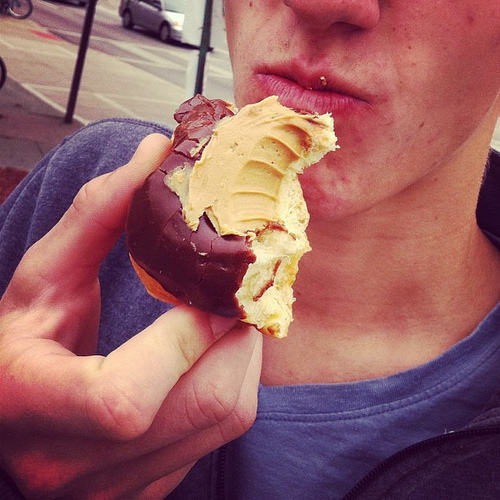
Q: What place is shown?
A: It is a city.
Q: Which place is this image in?
A: It is at the city.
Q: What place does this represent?
A: It represents the city.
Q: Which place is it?
A: It is a city.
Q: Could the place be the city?
A: Yes, it is the city.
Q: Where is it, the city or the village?
A: It is the city.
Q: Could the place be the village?
A: No, it is the city.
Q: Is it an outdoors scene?
A: Yes, it is outdoors.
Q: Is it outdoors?
A: Yes, it is outdoors.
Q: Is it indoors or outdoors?
A: It is outdoors.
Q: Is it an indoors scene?
A: No, it is outdoors.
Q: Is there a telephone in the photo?
A: No, there are no phones.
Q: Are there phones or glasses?
A: No, there are no phones or glasses.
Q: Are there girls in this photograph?
A: No, there are no girls.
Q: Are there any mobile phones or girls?
A: No, there are no girls or mobile phones.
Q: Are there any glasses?
A: No, there are no glasses.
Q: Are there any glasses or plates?
A: No, there are no glasses or plates.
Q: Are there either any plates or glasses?
A: No, there are no glasses or plates.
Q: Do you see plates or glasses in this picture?
A: No, there are no glasses or plates.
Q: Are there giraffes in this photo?
A: No, there are no giraffes.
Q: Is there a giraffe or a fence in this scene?
A: No, there are no giraffes or fences.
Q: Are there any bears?
A: No, there are no bears.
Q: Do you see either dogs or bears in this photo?
A: No, there are no bears or dogs.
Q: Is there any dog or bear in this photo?
A: No, there are no bears or dogs.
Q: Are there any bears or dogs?
A: No, there are no bears or dogs.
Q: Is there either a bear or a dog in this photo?
A: No, there are no bears or dogs.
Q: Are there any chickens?
A: No, there are no chickens.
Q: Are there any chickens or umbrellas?
A: No, there are no chickens or umbrellas.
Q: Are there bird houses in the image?
A: No, there are no bird houses.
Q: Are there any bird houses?
A: No, there are no bird houses.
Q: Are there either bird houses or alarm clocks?
A: No, there are no bird houses or alarm clocks.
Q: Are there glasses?
A: No, there are no glasses.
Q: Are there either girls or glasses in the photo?
A: No, there are no glasses or girls.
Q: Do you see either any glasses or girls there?
A: No, there are no glasses or girls.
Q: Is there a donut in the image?
A: Yes, there is a donut.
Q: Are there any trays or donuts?
A: Yes, there is a donut.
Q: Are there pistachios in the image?
A: No, there are no pistachios.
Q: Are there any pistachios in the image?
A: No, there are no pistachios.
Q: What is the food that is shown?
A: The food is a donut.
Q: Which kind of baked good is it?
A: The food is a donut.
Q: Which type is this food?
A: This is a donut.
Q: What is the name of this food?
A: This is a donut.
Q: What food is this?
A: This is a donut.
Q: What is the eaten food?
A: The food is a donut.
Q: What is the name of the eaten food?
A: The food is a donut.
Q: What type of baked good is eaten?
A: The baked good is a donut.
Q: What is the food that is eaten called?
A: The food is a donut.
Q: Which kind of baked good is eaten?
A: The baked good is a donut.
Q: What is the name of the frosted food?
A: The food is a donut.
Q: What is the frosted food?
A: The food is a donut.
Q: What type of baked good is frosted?
A: The baked good is a donut.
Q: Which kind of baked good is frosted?
A: The baked good is a donut.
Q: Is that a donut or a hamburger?
A: That is a donut.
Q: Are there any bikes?
A: Yes, there is a bike.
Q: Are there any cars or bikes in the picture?
A: Yes, there is a bike.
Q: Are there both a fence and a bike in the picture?
A: No, there is a bike but no fences.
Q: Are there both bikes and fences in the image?
A: No, there is a bike but no fences.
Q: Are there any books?
A: No, there are no books.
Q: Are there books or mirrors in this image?
A: No, there are no books or mirrors.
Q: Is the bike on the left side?
A: Yes, the bike is on the left of the image.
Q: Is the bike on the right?
A: No, the bike is on the left of the image.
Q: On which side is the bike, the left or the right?
A: The bike is on the left of the image.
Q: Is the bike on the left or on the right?
A: The bike is on the left of the image.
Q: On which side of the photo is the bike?
A: The bike is on the left of the image.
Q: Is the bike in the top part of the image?
A: Yes, the bike is in the top of the image.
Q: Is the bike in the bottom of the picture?
A: No, the bike is in the top of the image.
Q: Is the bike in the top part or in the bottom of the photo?
A: The bike is in the top of the image.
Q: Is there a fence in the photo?
A: No, there are no fences.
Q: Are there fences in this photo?
A: No, there are no fences.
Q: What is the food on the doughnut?
A: The food is peanut butter.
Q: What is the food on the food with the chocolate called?
A: The food is peanut butter.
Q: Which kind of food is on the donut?
A: The food is peanut butter.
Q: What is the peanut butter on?
A: The peanut butter is on the doughnut.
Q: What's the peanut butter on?
A: The peanut butter is on the doughnut.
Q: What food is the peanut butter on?
A: The peanut butter is on the doughnut.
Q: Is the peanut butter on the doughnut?
A: Yes, the peanut butter is on the doughnut.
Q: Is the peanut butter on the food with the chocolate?
A: Yes, the peanut butter is on the doughnut.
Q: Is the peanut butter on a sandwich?
A: No, the peanut butter is on the doughnut.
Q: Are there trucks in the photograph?
A: No, there are no trucks.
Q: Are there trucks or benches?
A: No, there are no trucks or benches.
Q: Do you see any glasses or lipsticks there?
A: No, there are no glasses or lipsticks.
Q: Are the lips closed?
A: Yes, the lips are closed.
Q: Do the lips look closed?
A: Yes, the lips are closed.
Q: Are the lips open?
A: No, the lips are closed.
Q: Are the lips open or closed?
A: The lips are closed.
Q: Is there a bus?
A: No, there are no buses.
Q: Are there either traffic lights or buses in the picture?
A: No, there are no buses or traffic lights.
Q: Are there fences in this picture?
A: No, there are no fences.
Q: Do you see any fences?
A: No, there are no fences.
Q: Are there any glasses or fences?
A: No, there are no fences or glasses.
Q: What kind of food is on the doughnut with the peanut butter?
A: The food is chocolate.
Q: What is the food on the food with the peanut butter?
A: The food is chocolate.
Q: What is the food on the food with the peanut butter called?
A: The food is chocolate.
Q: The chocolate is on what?
A: The chocolate is on the doughnut.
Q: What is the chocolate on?
A: The chocolate is on the doughnut.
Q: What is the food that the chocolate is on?
A: The food is a donut.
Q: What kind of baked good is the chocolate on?
A: The chocolate is on the donut.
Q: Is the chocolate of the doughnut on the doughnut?
A: Yes, the chocolate is on the doughnut.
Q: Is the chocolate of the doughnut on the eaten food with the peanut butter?
A: Yes, the chocolate is on the doughnut.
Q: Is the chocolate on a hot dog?
A: No, the chocolate is on the doughnut.